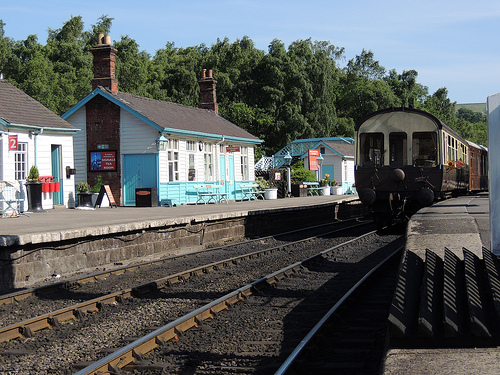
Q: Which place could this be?
A: It is a station.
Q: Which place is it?
A: It is a station.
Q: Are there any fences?
A: No, there are no fences.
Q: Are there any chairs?
A: Yes, there is a chair.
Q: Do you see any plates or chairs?
A: Yes, there is a chair.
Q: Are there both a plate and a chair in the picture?
A: No, there is a chair but no plates.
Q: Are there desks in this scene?
A: No, there are no desks.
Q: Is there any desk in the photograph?
A: No, there are no desks.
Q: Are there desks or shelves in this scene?
A: No, there are no desks or shelves.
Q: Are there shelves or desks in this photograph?
A: No, there are no desks or shelves.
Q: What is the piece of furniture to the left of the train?
A: The piece of furniture is a chair.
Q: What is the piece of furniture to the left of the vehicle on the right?
A: The piece of furniture is a chair.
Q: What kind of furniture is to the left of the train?
A: The piece of furniture is a chair.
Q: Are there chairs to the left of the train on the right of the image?
A: Yes, there is a chair to the left of the train.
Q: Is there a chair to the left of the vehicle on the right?
A: Yes, there is a chair to the left of the train.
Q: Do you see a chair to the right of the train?
A: No, the chair is to the left of the train.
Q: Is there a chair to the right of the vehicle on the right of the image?
A: No, the chair is to the left of the train.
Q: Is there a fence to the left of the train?
A: No, there is a chair to the left of the train.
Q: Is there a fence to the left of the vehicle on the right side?
A: No, there is a chair to the left of the train.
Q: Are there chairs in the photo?
A: Yes, there is a chair.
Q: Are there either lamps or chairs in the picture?
A: Yes, there is a chair.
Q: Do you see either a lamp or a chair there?
A: Yes, there is a chair.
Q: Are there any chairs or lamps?
A: Yes, there is a chair.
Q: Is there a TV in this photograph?
A: No, there are no televisions.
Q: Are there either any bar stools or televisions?
A: No, there are no televisions or bar stools.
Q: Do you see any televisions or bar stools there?
A: No, there are no televisions or bar stools.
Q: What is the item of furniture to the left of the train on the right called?
A: The piece of furniture is a chair.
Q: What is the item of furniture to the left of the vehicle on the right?
A: The piece of furniture is a chair.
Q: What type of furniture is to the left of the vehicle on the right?
A: The piece of furniture is a chair.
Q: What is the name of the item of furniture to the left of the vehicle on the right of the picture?
A: The piece of furniture is a chair.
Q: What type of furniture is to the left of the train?
A: The piece of furniture is a chair.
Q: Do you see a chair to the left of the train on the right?
A: Yes, there is a chair to the left of the train.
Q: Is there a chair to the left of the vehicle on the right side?
A: Yes, there is a chair to the left of the train.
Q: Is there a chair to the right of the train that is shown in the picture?
A: No, the chair is to the left of the train.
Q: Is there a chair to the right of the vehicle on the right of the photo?
A: No, the chair is to the left of the train.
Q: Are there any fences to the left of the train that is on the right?
A: No, there is a chair to the left of the train.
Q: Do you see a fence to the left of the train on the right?
A: No, there is a chair to the left of the train.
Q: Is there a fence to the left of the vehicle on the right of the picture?
A: No, there is a chair to the left of the train.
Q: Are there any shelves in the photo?
A: No, there are no shelves.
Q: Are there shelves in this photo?
A: No, there are no shelves.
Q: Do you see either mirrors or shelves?
A: No, there are no shelves or mirrors.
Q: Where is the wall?
A: The wall is at the station.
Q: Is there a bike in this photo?
A: No, there are no bikes.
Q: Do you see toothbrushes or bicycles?
A: No, there are no bicycles or toothbrushes.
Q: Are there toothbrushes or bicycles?
A: No, there are no bicycles or toothbrushes.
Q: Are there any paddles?
A: No, there are no paddles.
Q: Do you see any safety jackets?
A: No, there are no safety jackets.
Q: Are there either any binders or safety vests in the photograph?
A: No, there are no safety vests or binders.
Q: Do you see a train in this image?
A: Yes, there is a train.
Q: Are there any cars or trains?
A: Yes, there is a train.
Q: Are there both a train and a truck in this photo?
A: No, there is a train but no trucks.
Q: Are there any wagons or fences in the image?
A: No, there are no fences or wagons.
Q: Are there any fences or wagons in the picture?
A: No, there are no fences or wagons.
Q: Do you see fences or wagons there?
A: No, there are no fences or wagons.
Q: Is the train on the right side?
A: Yes, the train is on the right of the image.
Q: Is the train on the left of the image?
A: No, the train is on the right of the image.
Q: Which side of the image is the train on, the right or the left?
A: The train is on the right of the image.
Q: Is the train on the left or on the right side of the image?
A: The train is on the right of the image.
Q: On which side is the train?
A: The train is on the right of the image.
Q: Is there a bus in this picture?
A: No, there are no buses.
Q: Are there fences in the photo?
A: No, there are no fences.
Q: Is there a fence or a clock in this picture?
A: No, there are no fences or clocks.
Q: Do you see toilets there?
A: No, there are no toilets.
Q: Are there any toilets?
A: No, there are no toilets.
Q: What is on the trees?
A: The leaves are on the trees.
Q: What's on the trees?
A: The leaves are on the trees.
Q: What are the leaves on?
A: The leaves are on the trees.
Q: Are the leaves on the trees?
A: Yes, the leaves are on the trees.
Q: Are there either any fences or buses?
A: No, there are no fences or buses.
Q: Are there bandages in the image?
A: No, there are no bandages.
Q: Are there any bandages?
A: No, there are no bandages.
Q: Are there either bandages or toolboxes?
A: No, there are no bandages or toolboxes.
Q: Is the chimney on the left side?
A: Yes, the chimney is on the left of the image.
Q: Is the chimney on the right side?
A: No, the chimney is on the left of the image.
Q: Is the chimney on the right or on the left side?
A: The chimney is on the left of the image.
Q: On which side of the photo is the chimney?
A: The chimney is on the left of the image.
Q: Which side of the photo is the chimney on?
A: The chimney is on the left of the image.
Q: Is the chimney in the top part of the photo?
A: Yes, the chimney is in the top of the image.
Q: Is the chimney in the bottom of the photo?
A: No, the chimney is in the top of the image.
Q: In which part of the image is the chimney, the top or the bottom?
A: The chimney is in the top of the image.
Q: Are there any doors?
A: Yes, there is a door.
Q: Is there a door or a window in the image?
A: Yes, there is a door.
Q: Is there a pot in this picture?
A: Yes, there is a pot.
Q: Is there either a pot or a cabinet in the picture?
A: Yes, there is a pot.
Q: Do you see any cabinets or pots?
A: Yes, there is a pot.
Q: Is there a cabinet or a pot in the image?
A: Yes, there is a pot.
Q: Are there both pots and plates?
A: No, there is a pot but no plates.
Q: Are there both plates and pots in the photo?
A: No, there is a pot but no plates.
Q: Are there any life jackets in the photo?
A: No, there are no life jackets.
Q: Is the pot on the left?
A: Yes, the pot is on the left of the image.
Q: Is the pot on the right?
A: No, the pot is on the left of the image.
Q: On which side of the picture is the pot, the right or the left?
A: The pot is on the left of the image.